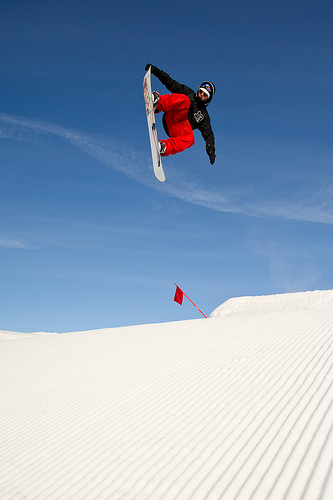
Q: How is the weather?
A: It is clear.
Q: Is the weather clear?
A: Yes, it is clear.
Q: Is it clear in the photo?
A: Yes, it is clear.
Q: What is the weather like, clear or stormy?
A: It is clear.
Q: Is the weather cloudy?
A: No, it is clear.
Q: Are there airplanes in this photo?
A: No, there are no airplanes.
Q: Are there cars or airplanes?
A: No, there are no airplanes or cars.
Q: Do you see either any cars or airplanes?
A: No, there are no airplanes or cars.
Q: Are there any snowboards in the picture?
A: Yes, there is a snowboard.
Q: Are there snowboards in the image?
A: Yes, there is a snowboard.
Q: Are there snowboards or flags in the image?
A: Yes, there is a snowboard.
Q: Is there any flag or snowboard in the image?
A: Yes, there is a snowboard.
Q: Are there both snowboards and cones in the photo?
A: No, there is a snowboard but no cones.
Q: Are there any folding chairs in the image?
A: No, there are no folding chairs.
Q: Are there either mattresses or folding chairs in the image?
A: No, there are no folding chairs or mattresses.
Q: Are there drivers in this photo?
A: No, there are no drivers.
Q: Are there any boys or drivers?
A: No, there are no drivers or boys.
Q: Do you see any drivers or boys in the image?
A: No, there are no drivers or boys.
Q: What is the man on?
A: The man is on the snowboard.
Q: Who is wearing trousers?
A: The man is wearing trousers.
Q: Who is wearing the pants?
A: The man is wearing trousers.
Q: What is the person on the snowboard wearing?
A: The man is wearing trousers.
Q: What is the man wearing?
A: The man is wearing trousers.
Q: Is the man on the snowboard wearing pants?
A: Yes, the man is wearing pants.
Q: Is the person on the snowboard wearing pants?
A: Yes, the man is wearing pants.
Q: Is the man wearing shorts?
A: No, the man is wearing pants.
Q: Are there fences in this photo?
A: No, there are no fences.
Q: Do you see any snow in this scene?
A: Yes, there is snow.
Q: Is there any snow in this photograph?
A: Yes, there is snow.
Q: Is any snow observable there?
A: Yes, there is snow.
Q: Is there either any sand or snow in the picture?
A: Yes, there is snow.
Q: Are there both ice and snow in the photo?
A: No, there is snow but no ice.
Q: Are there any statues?
A: No, there are no statues.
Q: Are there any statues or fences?
A: No, there are no statues or fences.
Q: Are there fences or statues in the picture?
A: No, there are no statues or fences.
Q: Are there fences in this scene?
A: No, there are no fences.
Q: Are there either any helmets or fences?
A: No, there are no fences or helmets.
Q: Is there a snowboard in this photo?
A: Yes, there is a snowboard.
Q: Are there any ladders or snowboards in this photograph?
A: Yes, there is a snowboard.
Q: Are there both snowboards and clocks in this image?
A: No, there is a snowboard but no clocks.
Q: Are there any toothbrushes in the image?
A: No, there are no toothbrushes.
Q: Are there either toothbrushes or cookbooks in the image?
A: No, there are no toothbrushes or cookbooks.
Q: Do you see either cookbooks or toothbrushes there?
A: No, there are no toothbrushes or cookbooks.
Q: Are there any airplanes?
A: No, there are no airplanes.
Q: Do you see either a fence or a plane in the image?
A: No, there are no airplanes or fences.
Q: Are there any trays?
A: No, there are no trays.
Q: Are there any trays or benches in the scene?
A: No, there are no trays or benches.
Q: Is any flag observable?
A: Yes, there is a flag.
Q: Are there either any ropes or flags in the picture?
A: Yes, there is a flag.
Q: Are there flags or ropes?
A: Yes, there is a flag.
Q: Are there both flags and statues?
A: No, there is a flag but no statues.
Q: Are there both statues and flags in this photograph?
A: No, there is a flag but no statues.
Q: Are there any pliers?
A: No, there are no pliers.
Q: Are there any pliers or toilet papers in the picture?
A: No, there are no pliers or toilet papers.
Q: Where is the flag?
A: The flag is in the snow.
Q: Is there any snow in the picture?
A: Yes, there is snow.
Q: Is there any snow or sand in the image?
A: Yes, there is snow.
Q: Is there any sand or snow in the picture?
A: Yes, there is snow.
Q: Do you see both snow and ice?
A: No, there is snow but no ice.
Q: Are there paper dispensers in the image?
A: No, there are no paper dispensers.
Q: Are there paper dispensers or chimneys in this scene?
A: No, there are no paper dispensers or chimneys.